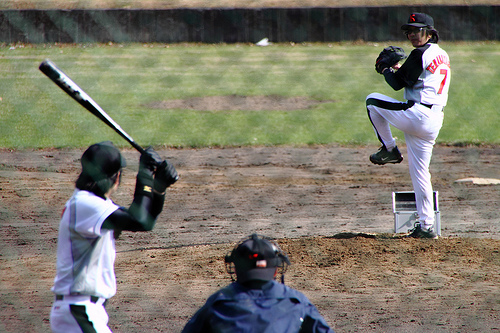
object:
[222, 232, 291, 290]
cap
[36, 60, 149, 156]
bat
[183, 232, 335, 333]
person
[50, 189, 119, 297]
shirt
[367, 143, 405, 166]
person/black shoes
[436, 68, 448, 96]
seven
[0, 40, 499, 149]
grass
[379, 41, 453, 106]
shirt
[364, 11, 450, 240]
person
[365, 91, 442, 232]
pants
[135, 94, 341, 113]
patch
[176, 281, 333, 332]
shirt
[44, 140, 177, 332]
person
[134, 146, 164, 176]
glove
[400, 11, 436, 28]
hat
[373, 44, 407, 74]
glove